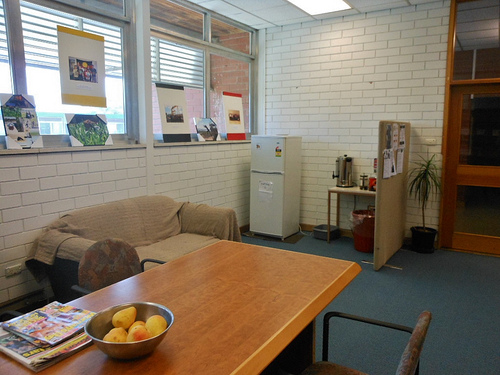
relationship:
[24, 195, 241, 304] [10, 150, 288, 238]
seat on wall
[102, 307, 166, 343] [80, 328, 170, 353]
pears in bowl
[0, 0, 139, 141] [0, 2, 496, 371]
blinds in room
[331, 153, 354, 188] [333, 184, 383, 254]
coffe pot on table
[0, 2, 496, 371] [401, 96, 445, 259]
room has corner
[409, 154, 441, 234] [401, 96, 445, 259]
plant in corner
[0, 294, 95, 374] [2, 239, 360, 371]
papers on table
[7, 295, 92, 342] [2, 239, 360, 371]
magazines on table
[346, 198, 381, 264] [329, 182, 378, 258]
can under table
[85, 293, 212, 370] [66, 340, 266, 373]
bowl/table on table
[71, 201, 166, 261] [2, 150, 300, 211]
seat against wall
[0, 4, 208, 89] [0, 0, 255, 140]
blinds on windows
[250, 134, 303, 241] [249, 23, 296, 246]
refrigerator in corner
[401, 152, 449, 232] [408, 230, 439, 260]
plant in pot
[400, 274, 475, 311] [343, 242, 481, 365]
carpet on floor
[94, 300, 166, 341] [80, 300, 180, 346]
pears in bowl.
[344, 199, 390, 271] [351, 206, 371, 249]
trash bag in can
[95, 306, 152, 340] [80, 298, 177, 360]
fruit in bowl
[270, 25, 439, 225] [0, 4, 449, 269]
wall in building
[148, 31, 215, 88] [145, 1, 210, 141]
blinds on window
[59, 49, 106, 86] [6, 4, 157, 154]
artwork on windowsill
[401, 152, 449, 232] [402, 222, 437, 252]
plant in black pot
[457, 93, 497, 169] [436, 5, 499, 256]
pane in door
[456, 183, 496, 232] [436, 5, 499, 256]
pane in door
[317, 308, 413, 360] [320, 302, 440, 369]
armrest of chair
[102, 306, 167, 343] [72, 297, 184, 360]
fruit in bowl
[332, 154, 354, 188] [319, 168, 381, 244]
coffe pot on table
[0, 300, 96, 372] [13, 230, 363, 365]
magazines on table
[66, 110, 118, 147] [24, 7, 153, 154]
icture on window sill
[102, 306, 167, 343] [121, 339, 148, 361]
fruit in bowl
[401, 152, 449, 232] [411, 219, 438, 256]
plant in pot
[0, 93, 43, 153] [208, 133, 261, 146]
photo on ledge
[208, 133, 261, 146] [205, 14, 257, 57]
ledge of window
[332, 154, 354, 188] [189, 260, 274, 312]
coffe pot on table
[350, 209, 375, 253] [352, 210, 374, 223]
trash bag with bag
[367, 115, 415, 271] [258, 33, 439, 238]
partition against wall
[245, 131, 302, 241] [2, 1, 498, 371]
refrigerator in a brake room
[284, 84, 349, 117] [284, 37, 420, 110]
bricks on walls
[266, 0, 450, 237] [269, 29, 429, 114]
bricks of a wall